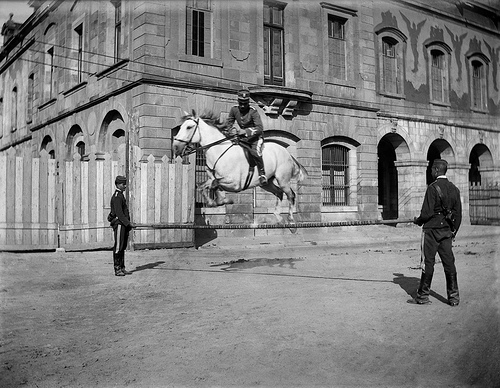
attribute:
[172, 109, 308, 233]
horse — white, jumping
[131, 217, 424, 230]
pole — wooden, long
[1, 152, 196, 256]
fence — wooden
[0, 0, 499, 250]
building — in the background, large, stone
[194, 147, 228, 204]
window — in the building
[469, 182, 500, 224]
fence — wooden, small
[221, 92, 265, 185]
man — jumping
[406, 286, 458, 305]
boots — black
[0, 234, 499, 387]
ground — gray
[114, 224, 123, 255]
stripe — white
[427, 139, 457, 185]
opening — dome shaped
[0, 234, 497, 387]
road — dirt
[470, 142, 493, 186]
doorway — arched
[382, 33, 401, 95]
window — arched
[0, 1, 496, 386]
photo — black